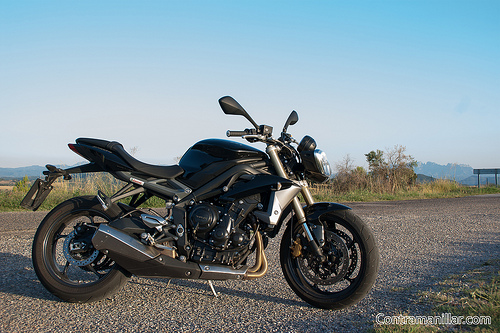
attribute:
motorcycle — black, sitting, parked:
[17, 89, 385, 314]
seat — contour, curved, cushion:
[73, 134, 187, 184]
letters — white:
[375, 309, 497, 329]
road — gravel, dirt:
[3, 195, 500, 332]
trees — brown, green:
[338, 147, 419, 198]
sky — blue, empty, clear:
[0, 1, 499, 186]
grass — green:
[0, 172, 496, 213]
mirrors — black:
[215, 91, 251, 124]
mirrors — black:
[281, 108, 304, 132]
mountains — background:
[388, 154, 499, 192]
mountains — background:
[3, 159, 83, 185]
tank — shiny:
[177, 135, 268, 179]